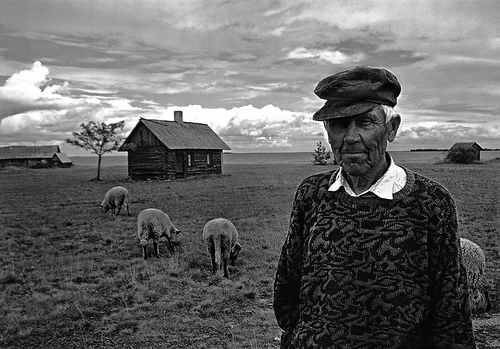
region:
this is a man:
[276, 60, 461, 342]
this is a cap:
[298, 70, 376, 115]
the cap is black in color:
[332, 87, 364, 102]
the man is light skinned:
[358, 132, 380, 160]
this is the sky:
[124, 33, 254, 100]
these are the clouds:
[231, 105, 291, 134]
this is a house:
[123, 120, 215, 182]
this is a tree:
[66, 121, 127, 173]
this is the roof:
[168, 121, 210, 140]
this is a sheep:
[205, 212, 250, 259]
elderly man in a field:
[268, 61, 465, 342]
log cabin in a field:
[105, 97, 242, 197]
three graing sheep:
[94, 174, 239, 288]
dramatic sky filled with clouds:
[4, 39, 84, 114]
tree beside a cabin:
[72, 113, 129, 185]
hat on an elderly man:
[303, 43, 406, 133]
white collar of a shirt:
[329, 166, 412, 209]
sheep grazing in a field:
[198, 211, 245, 282]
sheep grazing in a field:
[135, 209, 186, 263]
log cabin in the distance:
[442, 133, 499, 189]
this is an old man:
[276, 59, 442, 338]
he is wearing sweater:
[290, 205, 415, 345]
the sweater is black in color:
[301, 201, 426, 336]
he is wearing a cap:
[301, 60, 388, 112]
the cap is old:
[323, 60, 391, 107]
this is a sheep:
[198, 216, 240, 278]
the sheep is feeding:
[203, 218, 241, 275]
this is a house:
[130, 110, 230, 177]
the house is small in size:
[125, 120, 219, 180]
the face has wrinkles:
[368, 127, 386, 153]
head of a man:
[299, 67, 419, 182]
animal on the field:
[201, 202, 261, 276]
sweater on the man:
[269, 198, 414, 320]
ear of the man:
[378, 106, 411, 151]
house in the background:
[117, 97, 266, 199]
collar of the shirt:
[320, 158, 416, 208]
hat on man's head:
[308, 68, 403, 125]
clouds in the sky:
[134, 14, 256, 84]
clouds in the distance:
[5, 60, 82, 124]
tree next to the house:
[72, 117, 119, 189]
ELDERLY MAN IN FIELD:
[256, 12, 383, 334]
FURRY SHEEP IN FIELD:
[102, 169, 131, 219]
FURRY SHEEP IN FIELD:
[131, 200, 189, 259]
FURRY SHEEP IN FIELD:
[197, 186, 244, 287]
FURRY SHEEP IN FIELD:
[454, 228, 494, 304]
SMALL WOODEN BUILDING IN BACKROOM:
[129, 94, 222, 194]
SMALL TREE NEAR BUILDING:
[81, 110, 123, 187]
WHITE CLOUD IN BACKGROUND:
[223, 110, 318, 173]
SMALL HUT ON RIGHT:
[445, 138, 492, 160]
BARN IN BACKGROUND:
[4, 148, 71, 167]